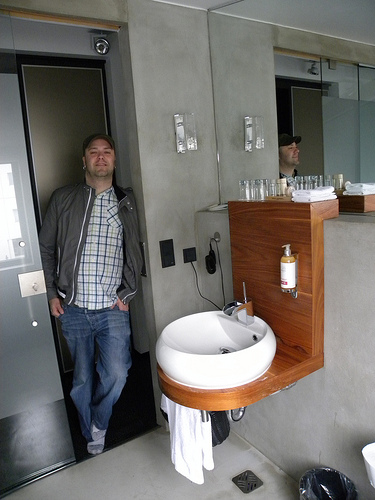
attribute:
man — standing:
[42, 122, 138, 426]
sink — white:
[156, 308, 286, 389]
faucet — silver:
[211, 287, 261, 323]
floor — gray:
[60, 468, 179, 497]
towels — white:
[157, 401, 225, 486]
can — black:
[287, 462, 362, 498]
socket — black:
[176, 247, 200, 264]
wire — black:
[178, 267, 215, 305]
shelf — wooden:
[228, 201, 348, 246]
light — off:
[169, 108, 203, 159]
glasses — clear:
[236, 181, 274, 202]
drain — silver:
[228, 468, 264, 493]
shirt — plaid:
[66, 185, 122, 305]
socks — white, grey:
[85, 420, 106, 453]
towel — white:
[154, 395, 218, 466]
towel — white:
[155, 395, 209, 485]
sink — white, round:
[128, 258, 313, 403]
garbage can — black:
[292, 465, 360, 499]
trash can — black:
[286, 457, 362, 498]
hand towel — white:
[156, 390, 221, 489]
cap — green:
[82, 132, 114, 154]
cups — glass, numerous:
[236, 173, 335, 200]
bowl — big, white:
[155, 307, 277, 390]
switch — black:
[161, 237, 185, 270]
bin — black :
[292, 459, 357, 497]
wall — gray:
[133, 12, 211, 116]